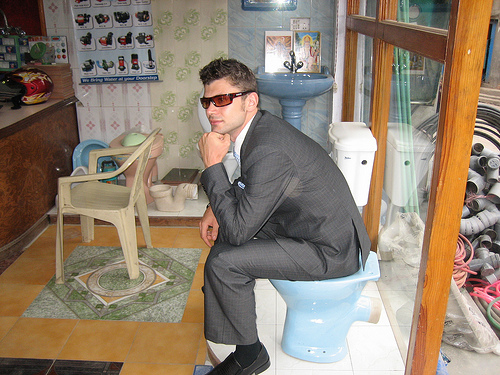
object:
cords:
[455, 233, 500, 328]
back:
[326, 121, 378, 212]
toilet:
[0, 0, 500, 375]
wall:
[32, 0, 407, 187]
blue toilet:
[266, 251, 382, 365]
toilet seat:
[269, 249, 380, 303]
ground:
[0, 213, 403, 375]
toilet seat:
[108, 132, 165, 178]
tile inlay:
[20, 242, 201, 324]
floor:
[0, 216, 217, 374]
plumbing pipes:
[409, 102, 500, 321]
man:
[193, 58, 371, 375]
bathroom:
[0, 0, 500, 375]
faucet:
[284, 49, 305, 73]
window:
[340, 0, 491, 375]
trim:
[418, 142, 476, 307]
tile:
[0, 217, 402, 374]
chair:
[55, 127, 161, 286]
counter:
[0, 94, 80, 266]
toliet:
[266, 250, 381, 365]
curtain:
[391, 0, 417, 219]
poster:
[68, 1, 158, 85]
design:
[21, 245, 203, 322]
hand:
[196, 131, 230, 165]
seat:
[265, 249, 384, 365]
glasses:
[198, 89, 257, 109]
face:
[200, 80, 247, 135]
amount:
[409, 102, 499, 354]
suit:
[195, 110, 372, 344]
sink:
[254, 70, 333, 102]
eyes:
[216, 96, 226, 103]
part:
[357, 294, 384, 323]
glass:
[351, 2, 457, 368]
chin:
[211, 126, 227, 135]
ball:
[120, 133, 147, 147]